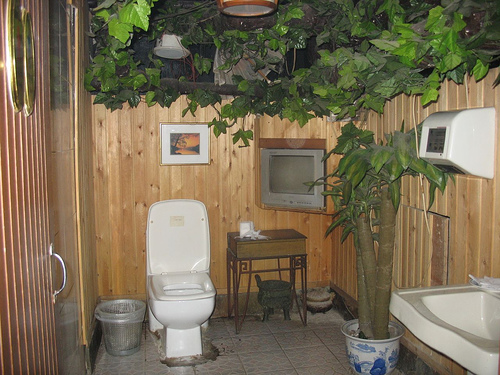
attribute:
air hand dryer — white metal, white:
[422, 104, 491, 180]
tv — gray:
[256, 138, 332, 213]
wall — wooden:
[239, 175, 253, 188]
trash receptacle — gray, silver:
[87, 302, 156, 355]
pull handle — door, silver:
[49, 238, 68, 304]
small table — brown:
[229, 229, 309, 310]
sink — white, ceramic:
[407, 292, 494, 358]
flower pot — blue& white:
[343, 327, 402, 366]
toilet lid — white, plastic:
[150, 204, 206, 268]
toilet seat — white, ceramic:
[151, 278, 226, 297]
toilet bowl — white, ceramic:
[152, 307, 210, 359]